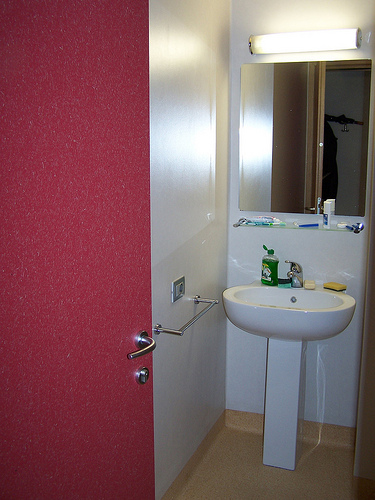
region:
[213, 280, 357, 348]
the sink in the bathroom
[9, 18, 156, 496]
the door is open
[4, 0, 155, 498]
the door is red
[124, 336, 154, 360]
the handle on the door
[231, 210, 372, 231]
toiletries on the shelf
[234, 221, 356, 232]
the shelf is glass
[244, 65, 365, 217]
the mirror on the wall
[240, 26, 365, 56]
the light above the mirror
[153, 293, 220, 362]
the empty rod on the wall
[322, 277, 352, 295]
the sponge on the sink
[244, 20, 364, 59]
a bright light above the mirror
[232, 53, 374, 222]
a mirror on the wall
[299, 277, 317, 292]
a bar of soap on the sink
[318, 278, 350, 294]
a sponge sitting on the sink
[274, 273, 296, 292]
a green and blue sponge on the sink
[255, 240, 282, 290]
a bottle with green liquid in it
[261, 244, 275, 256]
the green lid to the plastic bottle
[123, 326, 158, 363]
the door knob to the door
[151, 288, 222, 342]
a towel rack on the wall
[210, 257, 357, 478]
a small white sink up against the wall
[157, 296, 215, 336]
A railing in the bathroom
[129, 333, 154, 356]
A handle on the door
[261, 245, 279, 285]
Soap next to the faucet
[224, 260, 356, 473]
A sink by the wall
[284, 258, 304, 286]
A faucet on the sink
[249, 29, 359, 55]
A light above the sink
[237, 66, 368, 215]
A mirror on the wall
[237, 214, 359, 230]
A shelf above the sink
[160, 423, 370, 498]
The floor in the bathroom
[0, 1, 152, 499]
A red door by the sink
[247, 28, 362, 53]
A bathroom light fixture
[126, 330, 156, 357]
A metal door handle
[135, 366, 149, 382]
A key and lock on a door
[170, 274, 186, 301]
Metal light switch in a bathroom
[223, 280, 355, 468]
A white sink in a bathroom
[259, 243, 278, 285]
A bottle of green soap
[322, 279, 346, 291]
A yellow and green sponge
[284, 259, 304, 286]
A metal faucet on a bathroom sink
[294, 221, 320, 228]
A blue razor for shaving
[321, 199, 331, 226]
A bottle of shaving cream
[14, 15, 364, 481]
Bathroom inside of a ressidence.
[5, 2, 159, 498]
Red bathroom door with a stainless still door handle.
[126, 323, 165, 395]
Stainless steel door knob and lock.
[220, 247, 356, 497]
White pedestal sink.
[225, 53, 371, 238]
Large bathroom mirror reflecting the inside of a closet.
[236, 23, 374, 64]
Fluorescent bathroom light.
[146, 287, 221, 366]
Stainless steel towel bar.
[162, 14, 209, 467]
Bright white bathroom wall.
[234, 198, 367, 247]
Glass floating shelf inside of a bathroom.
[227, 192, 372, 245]
Personal care items resting upon a glass floating shelf.